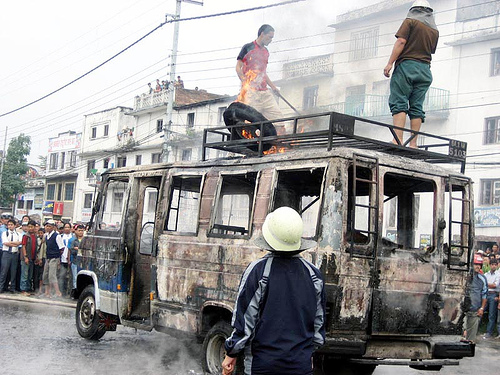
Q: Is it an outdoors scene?
A: Yes, it is outdoors.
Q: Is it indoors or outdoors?
A: It is outdoors.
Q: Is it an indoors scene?
A: No, it is outdoors.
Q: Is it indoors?
A: No, it is outdoors.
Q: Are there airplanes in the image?
A: No, there are no airplanes.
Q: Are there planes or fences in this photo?
A: No, there are no planes or fences.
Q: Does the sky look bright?
A: Yes, the sky is bright.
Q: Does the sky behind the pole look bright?
A: Yes, the sky is bright.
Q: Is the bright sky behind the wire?
A: Yes, the sky is behind the wire.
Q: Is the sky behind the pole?
A: Yes, the sky is behind the pole.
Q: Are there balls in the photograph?
A: No, there are no balls.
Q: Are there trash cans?
A: No, there are no trash cans.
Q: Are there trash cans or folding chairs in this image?
A: No, there are no trash cans or folding chairs.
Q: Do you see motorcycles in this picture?
A: No, there are no motorcycles.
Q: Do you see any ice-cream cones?
A: No, there are no ice-cream cones.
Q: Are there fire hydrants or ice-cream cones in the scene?
A: No, there are no ice-cream cones or fire hydrants.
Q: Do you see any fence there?
A: No, there are no fences.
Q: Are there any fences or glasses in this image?
A: No, there are no fences or glasses.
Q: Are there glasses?
A: No, there are no glasses.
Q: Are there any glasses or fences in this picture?
A: No, there are no glasses or fences.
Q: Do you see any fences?
A: No, there are no fences.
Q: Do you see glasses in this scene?
A: No, there are no glasses.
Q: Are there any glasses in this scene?
A: No, there are no glasses.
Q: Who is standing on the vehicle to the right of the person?
A: The man is standing on the car.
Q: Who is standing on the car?
A: The man is standing on the car.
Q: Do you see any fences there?
A: No, there are no fences.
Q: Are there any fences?
A: No, there are no fences.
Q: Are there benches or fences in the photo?
A: No, there are no fences or benches.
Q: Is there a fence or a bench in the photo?
A: No, there are no fences or benches.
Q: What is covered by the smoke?
A: The street is covered by the smoke.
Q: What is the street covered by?
A: The street is covered by the smoke.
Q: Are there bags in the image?
A: No, there are no bags.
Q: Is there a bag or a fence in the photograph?
A: No, there are no bags or fences.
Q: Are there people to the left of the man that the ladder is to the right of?
A: Yes, there is a person to the left of the man.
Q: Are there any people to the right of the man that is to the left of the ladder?
A: No, the person is to the left of the man.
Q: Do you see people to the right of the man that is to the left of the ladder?
A: No, the person is to the left of the man.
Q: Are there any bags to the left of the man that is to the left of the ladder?
A: No, there is a person to the left of the man.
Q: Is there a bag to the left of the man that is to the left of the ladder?
A: No, there is a person to the left of the man.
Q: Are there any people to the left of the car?
A: Yes, there is a person to the left of the car.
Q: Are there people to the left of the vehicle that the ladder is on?
A: Yes, there is a person to the left of the car.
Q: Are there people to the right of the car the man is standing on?
A: No, the person is to the left of the car.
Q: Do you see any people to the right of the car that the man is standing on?
A: No, the person is to the left of the car.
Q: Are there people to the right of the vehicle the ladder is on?
A: No, the person is to the left of the car.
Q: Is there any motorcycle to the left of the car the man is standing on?
A: No, there is a person to the left of the car.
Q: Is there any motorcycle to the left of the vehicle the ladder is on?
A: No, there is a person to the left of the car.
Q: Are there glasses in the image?
A: No, there are no glasses.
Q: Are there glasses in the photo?
A: No, there are no glasses.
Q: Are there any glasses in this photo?
A: No, there are no glasses.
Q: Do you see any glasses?
A: No, there are no glasses.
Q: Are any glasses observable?
A: No, there are no glasses.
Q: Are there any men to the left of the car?
A: Yes, there is a man to the left of the car.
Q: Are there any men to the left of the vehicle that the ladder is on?
A: Yes, there is a man to the left of the car.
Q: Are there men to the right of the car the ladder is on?
A: No, the man is to the left of the car.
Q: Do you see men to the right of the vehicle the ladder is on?
A: No, the man is to the left of the car.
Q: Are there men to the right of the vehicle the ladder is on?
A: No, the man is to the left of the car.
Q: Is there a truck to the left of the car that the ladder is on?
A: No, there is a man to the left of the car.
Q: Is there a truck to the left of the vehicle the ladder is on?
A: No, there is a man to the left of the car.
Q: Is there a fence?
A: No, there are no fences.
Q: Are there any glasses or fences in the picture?
A: No, there are no fences or glasses.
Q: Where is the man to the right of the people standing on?
A: The man is standing on the car.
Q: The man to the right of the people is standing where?
A: The man is standing on the car.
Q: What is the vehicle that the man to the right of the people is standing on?
A: The vehicle is a car.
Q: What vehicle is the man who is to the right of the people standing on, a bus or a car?
A: The man is standing on a car.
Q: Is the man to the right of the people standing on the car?
A: Yes, the man is standing on the car.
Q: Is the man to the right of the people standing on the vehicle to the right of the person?
A: Yes, the man is standing on the car.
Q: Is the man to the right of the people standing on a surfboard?
A: No, the man is standing on the car.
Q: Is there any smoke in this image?
A: Yes, there is smoke.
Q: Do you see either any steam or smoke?
A: Yes, there is smoke.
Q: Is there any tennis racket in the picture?
A: No, there are no rackets.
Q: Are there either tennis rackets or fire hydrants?
A: No, there are no tennis rackets or fire hydrants.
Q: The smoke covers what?
A: The smoke covers the street.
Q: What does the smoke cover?
A: The smoke covers the street.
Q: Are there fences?
A: No, there are no fences.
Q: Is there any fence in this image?
A: No, there are no fences.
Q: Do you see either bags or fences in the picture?
A: No, there are no fences or bags.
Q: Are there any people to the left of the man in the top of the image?
A: Yes, there are people to the left of the man.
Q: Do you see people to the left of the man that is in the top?
A: Yes, there are people to the left of the man.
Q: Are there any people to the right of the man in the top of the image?
A: No, the people are to the left of the man.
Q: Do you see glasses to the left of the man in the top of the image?
A: No, there are people to the left of the man.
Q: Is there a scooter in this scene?
A: No, there are no scooters.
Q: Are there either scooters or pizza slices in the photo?
A: No, there are no scooters or pizza slices.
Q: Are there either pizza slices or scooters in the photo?
A: No, there are no scooters or pizza slices.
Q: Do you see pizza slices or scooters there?
A: No, there are no scooters or pizza slices.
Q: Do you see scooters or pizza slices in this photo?
A: No, there are no scooters or pizza slices.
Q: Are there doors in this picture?
A: Yes, there is a door.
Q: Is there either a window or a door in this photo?
A: Yes, there is a door.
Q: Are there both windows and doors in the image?
A: Yes, there are both a door and a window.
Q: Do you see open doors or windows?
A: Yes, there is an open door.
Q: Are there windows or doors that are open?
A: Yes, the door is open.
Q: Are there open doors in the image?
A: Yes, there is an open door.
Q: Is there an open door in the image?
A: Yes, there is an open door.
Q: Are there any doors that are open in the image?
A: Yes, there is an open door.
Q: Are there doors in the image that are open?
A: Yes, there is a door that is open.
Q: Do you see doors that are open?
A: Yes, there is a door that is open.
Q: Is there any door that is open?
A: Yes, there is a door that is open.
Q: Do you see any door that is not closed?
A: Yes, there is a open door.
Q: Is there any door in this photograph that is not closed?
A: Yes, there is a open door.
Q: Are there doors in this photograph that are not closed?
A: Yes, there is a open door.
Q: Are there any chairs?
A: No, there are no chairs.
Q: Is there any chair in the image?
A: No, there are no chairs.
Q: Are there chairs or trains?
A: No, there are no chairs or trains.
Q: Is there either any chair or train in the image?
A: No, there are no chairs or trains.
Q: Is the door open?
A: Yes, the door is open.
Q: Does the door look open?
A: Yes, the door is open.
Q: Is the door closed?
A: No, the door is open.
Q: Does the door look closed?
A: No, the door is open.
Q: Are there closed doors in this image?
A: No, there is a door but it is open.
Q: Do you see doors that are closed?
A: No, there is a door but it is open.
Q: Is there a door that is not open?
A: No, there is a door but it is open.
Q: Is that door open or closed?
A: The door is open.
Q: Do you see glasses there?
A: No, there are no glasses.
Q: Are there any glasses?
A: No, there are no glasses.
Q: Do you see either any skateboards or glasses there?
A: No, there are no glasses or skateboards.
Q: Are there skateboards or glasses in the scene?
A: No, there are no glasses or skateboards.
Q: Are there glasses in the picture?
A: No, there are no glasses.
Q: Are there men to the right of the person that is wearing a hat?
A: Yes, there is a man to the right of the person.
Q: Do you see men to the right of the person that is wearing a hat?
A: Yes, there is a man to the right of the person.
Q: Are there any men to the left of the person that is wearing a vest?
A: No, the man is to the right of the person.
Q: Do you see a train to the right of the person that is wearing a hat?
A: No, there is a man to the right of the person.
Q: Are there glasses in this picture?
A: No, there are no glasses.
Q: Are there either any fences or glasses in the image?
A: No, there are no glasses or fences.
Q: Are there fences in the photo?
A: No, there are no fences.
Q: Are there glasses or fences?
A: No, there are no fences or glasses.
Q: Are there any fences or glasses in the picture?
A: No, there are no fences or glasses.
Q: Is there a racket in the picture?
A: No, there are no rackets.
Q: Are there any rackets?
A: No, there are no rackets.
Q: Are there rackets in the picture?
A: No, there are no rackets.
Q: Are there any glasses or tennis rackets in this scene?
A: No, there are no tennis rackets or glasses.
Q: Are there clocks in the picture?
A: No, there are no clocks.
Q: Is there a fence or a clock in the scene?
A: No, there are no clocks or fences.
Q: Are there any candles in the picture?
A: No, there are no candles.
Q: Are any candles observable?
A: No, there are no candles.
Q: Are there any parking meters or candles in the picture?
A: No, there are no candles or parking meters.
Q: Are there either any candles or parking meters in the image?
A: No, there are no candles or parking meters.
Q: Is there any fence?
A: No, there are no fences.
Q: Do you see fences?
A: No, there are no fences.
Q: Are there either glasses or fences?
A: No, there are no fences or glasses.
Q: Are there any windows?
A: Yes, there is a window.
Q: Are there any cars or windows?
A: Yes, there is a window.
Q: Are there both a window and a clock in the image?
A: No, there is a window but no clocks.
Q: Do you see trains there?
A: No, there are no trains.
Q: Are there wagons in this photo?
A: No, there are no wagons.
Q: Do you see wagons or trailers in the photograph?
A: No, there are no wagons or trailers.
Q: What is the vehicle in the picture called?
A: The vehicle is a car.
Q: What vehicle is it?
A: The vehicle is a car.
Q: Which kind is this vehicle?
A: That is a car.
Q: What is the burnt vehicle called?
A: The vehicle is a car.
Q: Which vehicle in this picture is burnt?
A: The vehicle is a car.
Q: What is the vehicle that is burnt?
A: The vehicle is a car.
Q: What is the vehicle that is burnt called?
A: The vehicle is a car.